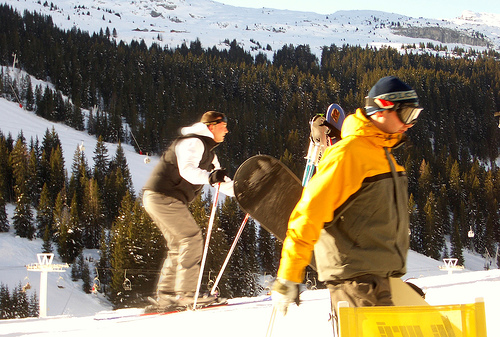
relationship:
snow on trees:
[66, 135, 86, 150] [190, 57, 241, 75]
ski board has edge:
[242, 161, 271, 196] [252, 150, 271, 166]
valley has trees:
[151, 36, 249, 69] [446, 61, 470, 106]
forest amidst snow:
[245, 103, 284, 134] [190, 20, 216, 29]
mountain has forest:
[139, 24, 383, 49] [62, 47, 123, 85]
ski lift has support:
[7, 62, 32, 101] [72, 259, 120, 272]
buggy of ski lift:
[17, 280, 41, 295] [7, 62, 32, 101]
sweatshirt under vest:
[188, 127, 208, 133] [167, 145, 177, 167]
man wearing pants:
[138, 109, 238, 307] [144, 206, 203, 273]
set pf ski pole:
[204, 204, 242, 261] [193, 185, 220, 308]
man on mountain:
[138, 109, 238, 307] [139, 24, 383, 49]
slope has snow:
[57, 131, 100, 154] [66, 135, 86, 150]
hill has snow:
[37, 79, 63, 103] [66, 135, 86, 150]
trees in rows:
[58, 57, 90, 75] [47, 93, 81, 126]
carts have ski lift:
[87, 278, 112, 297] [7, 62, 32, 101]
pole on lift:
[40, 272, 48, 312] [122, 282, 139, 290]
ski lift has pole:
[7, 62, 32, 101] [40, 272, 48, 312]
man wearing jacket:
[138, 109, 238, 307] [339, 158, 392, 241]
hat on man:
[374, 94, 408, 106] [138, 109, 238, 307]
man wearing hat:
[138, 109, 238, 307] [374, 94, 408, 106]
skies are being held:
[294, 130, 321, 173] [269, 266, 298, 289]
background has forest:
[80, 60, 183, 88] [448, 71, 483, 111]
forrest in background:
[66, 41, 282, 87] [80, 60, 183, 88]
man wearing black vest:
[181, 105, 239, 146] [142, 133, 224, 204]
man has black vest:
[138, 109, 238, 307] [161, 169, 194, 205]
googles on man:
[396, 106, 406, 116] [138, 109, 238, 307]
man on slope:
[138, 109, 238, 307] [240, 291, 269, 311]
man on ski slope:
[138, 109, 238, 307] [45, 294, 102, 311]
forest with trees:
[62, 47, 123, 85] [446, 61, 470, 106]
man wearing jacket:
[138, 109, 238, 307] [346, 203, 400, 268]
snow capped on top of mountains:
[162, 26, 185, 36] [378, 22, 489, 49]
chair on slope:
[210, 284, 223, 297] [57, 131, 100, 154]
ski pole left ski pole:
[193, 185, 220, 308] [198, 199, 211, 309]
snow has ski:
[82, 12, 105, 16] [160, 302, 231, 310]